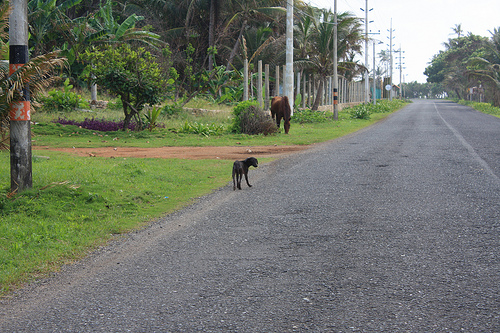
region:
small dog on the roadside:
[215, 149, 267, 191]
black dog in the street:
[224, 140, 268, 202]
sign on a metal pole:
[9, 93, 32, 125]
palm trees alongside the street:
[69, 5, 149, 47]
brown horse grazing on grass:
[264, 88, 302, 140]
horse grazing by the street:
[265, 91, 297, 134]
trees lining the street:
[425, 22, 499, 121]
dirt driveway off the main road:
[119, 131, 324, 178]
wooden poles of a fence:
[241, 48, 391, 112]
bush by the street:
[221, 93, 283, 130]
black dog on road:
[194, 135, 294, 203]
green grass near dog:
[60, 161, 207, 253]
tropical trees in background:
[72, 4, 354, 116]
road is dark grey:
[300, 125, 411, 305]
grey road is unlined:
[254, 100, 498, 275]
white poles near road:
[255, 8, 365, 112]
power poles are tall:
[0, 15, 405, 216]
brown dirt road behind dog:
[37, 133, 277, 164]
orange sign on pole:
[0, 74, 44, 125]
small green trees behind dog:
[60, 44, 208, 141]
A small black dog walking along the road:
[228, 150, 260, 192]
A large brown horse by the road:
[268, 89, 296, 134]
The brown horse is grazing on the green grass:
[267, 93, 300, 135]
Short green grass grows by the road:
[296, 120, 343, 141]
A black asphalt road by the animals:
[316, 140, 486, 320]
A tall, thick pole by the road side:
[3, 0, 58, 197]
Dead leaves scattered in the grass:
[59, 126, 127, 141]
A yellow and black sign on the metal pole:
[329, 85, 341, 105]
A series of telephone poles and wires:
[330, 1, 414, 108]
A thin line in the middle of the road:
[434, 103, 496, 178]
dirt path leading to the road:
[14, 140, 328, 165]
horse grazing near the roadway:
[264, 91, 293, 133]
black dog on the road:
[229, 150, 262, 195]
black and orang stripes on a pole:
[6, 41, 31, 126]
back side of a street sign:
[382, 82, 390, 92]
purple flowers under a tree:
[53, 114, 138, 135]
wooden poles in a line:
[241, 54, 373, 112]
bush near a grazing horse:
[229, 98, 279, 139]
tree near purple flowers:
[80, 38, 176, 135]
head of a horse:
[283, 113, 294, 135]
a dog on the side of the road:
[226, 154, 260, 194]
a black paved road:
[8, 94, 497, 332]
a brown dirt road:
[44, 140, 308, 158]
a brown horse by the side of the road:
[265, 89, 294, 135]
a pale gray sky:
[302, 1, 498, 84]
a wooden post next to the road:
[329, 0, 342, 118]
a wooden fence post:
[252, 51, 265, 112]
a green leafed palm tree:
[82, 6, 159, 106]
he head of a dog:
[248, 155, 261, 164]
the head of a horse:
[281, 113, 294, 134]